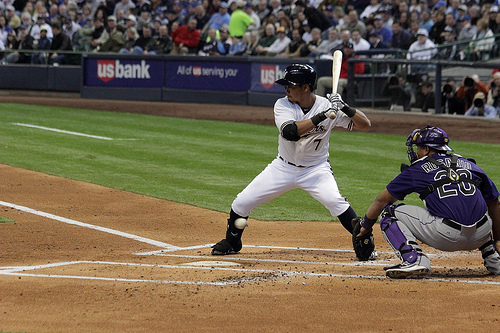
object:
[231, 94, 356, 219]
uniform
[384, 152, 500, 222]
jersey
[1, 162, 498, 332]
dirt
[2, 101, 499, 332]
ground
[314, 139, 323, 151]
number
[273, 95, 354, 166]
jersey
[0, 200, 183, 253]
chalk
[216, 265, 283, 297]
gravel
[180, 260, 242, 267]
home plate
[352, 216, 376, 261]
glove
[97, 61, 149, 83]
ad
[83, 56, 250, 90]
banner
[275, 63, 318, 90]
helmet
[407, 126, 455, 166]
helmet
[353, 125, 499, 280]
baseball player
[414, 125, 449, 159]
head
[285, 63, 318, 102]
head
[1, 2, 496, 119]
spectators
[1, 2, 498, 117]
bleachers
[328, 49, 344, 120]
bat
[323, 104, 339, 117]
hands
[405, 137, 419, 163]
mask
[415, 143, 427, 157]
catcher's face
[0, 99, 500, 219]
grass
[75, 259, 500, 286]
lines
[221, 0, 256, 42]
person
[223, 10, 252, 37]
shirt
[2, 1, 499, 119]
stands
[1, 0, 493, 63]
crowd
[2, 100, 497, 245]
lawn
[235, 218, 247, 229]
ball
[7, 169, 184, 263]
baseline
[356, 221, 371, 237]
hand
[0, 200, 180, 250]
line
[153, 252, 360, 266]
line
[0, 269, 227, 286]
line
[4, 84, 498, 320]
field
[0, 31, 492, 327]
game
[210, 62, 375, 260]
baseball player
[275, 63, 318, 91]
hat